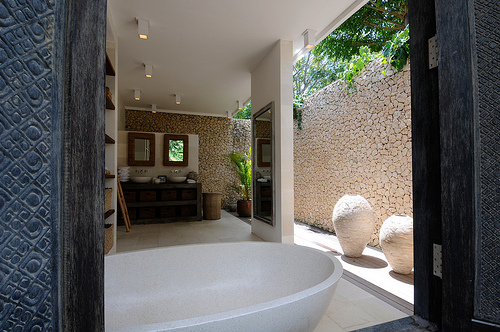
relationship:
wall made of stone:
[311, 95, 430, 194] [377, 116, 391, 134]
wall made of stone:
[311, 95, 430, 194] [373, 153, 387, 172]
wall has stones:
[294, 24, 417, 252] [308, 107, 438, 208]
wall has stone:
[294, 24, 417, 252] [390, 147, 397, 156]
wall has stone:
[294, 24, 417, 252] [386, 89, 398, 104]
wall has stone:
[294, 24, 417, 252] [385, 121, 404, 136]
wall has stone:
[294, 24, 417, 252] [345, 122, 357, 131]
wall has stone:
[294, 24, 417, 252] [354, 75, 366, 85]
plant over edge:
[292, 95, 302, 127] [291, 43, 399, 100]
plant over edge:
[229, 98, 254, 121] [291, 43, 399, 100]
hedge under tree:
[278, 2, 420, 109] [265, 34, 432, 274]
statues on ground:
[327, 193, 414, 280] [307, 223, 328, 245]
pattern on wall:
[0, 0, 66, 331] [125, 110, 260, 205]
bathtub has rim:
[110, 233, 352, 330] [299, 276, 329, 301]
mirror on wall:
[164, 132, 189, 165] [188, 132, 198, 171]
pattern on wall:
[4, 2, 64, 329] [0, 51, 61, 330]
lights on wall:
[112, 17, 179, 114] [129, 115, 321, 263]